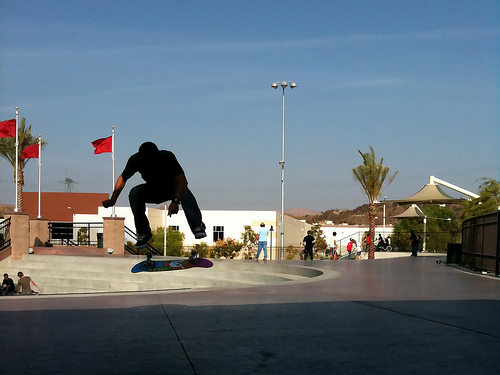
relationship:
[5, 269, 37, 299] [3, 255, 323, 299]
people sitting on stairs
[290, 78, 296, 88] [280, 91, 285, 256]
light on pole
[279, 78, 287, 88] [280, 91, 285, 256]
light on pole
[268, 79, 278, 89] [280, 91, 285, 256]
light on pole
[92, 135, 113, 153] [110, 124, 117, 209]
flag on pole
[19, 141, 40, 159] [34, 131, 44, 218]
flag on pole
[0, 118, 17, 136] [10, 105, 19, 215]
flag on pole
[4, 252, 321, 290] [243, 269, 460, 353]
steps on platform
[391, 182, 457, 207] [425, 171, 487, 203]
umbrella on pole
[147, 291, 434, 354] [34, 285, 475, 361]
shadow on cement surface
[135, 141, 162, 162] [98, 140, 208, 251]
head has skater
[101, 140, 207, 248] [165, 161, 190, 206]
airborne man has arm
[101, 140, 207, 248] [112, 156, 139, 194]
airborne man has arm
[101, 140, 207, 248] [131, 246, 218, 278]
airborne man riding skateboard